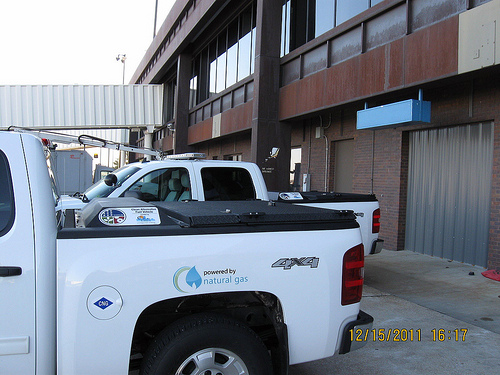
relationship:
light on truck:
[343, 245, 366, 308] [2, 129, 363, 371]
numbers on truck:
[273, 255, 321, 270] [2, 129, 363, 371]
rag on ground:
[481, 267, 500, 283] [289, 246, 499, 373]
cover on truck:
[151, 197, 362, 235] [2, 129, 363, 371]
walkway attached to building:
[2, 81, 169, 131] [129, 0, 499, 269]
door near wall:
[407, 121, 493, 267] [301, 118, 407, 250]